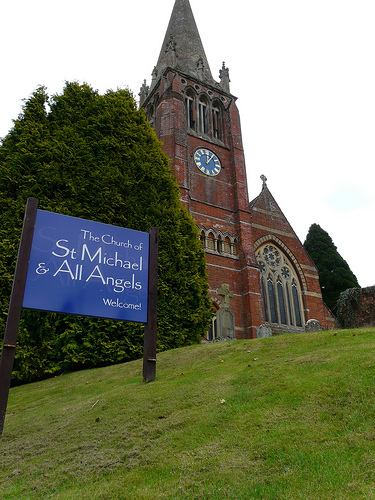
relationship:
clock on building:
[177, 129, 244, 179] [36, 19, 336, 402]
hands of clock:
[205, 149, 217, 165] [192, 144, 223, 176]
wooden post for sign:
[143, 228, 158, 382] [23, 207, 149, 327]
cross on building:
[260, 174, 268, 185] [137, 0, 338, 341]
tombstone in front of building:
[217, 309, 234, 340] [137, 0, 338, 341]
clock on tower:
[193, 146, 222, 177] [139, 0, 254, 340]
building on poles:
[137, 0, 338, 341] [6, 188, 169, 383]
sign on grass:
[0, 196, 158, 433] [0, 324, 372, 498]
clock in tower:
[193, 146, 222, 177] [138, 0, 268, 341]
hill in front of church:
[1, 326, 373, 499] [136, 1, 343, 346]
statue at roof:
[163, 30, 179, 68] [147, 0, 222, 80]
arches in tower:
[180, 85, 229, 147] [137, 12, 259, 83]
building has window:
[137, 0, 338, 341] [227, 226, 315, 327]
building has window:
[138, 0, 374, 343] [205, 230, 214, 250]